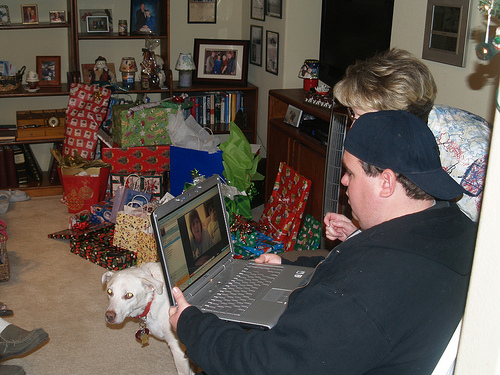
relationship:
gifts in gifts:
[37, 78, 331, 268] [37, 78, 331, 268]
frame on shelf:
[180, 34, 257, 94] [27, 6, 266, 142]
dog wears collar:
[98, 250, 192, 355] [107, 251, 158, 358]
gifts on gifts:
[37, 78, 331, 268] [37, 78, 331, 268]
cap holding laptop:
[167, 108, 489, 344] [133, 176, 321, 335]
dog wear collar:
[98, 250, 192, 355] [107, 251, 158, 358]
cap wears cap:
[167, 108, 489, 344] [338, 98, 485, 223]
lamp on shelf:
[106, 49, 225, 116] [27, 6, 266, 142]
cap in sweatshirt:
[167, 108, 489, 344] [171, 227, 460, 353]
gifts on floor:
[37, 78, 331, 268] [15, 98, 175, 370]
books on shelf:
[165, 89, 257, 140] [27, 6, 266, 142]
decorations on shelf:
[87, 48, 201, 96] [27, 6, 266, 142]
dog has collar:
[98, 250, 192, 355] [107, 251, 158, 358]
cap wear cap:
[167, 108, 489, 344] [338, 98, 485, 223]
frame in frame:
[180, 34, 257, 94] [170, 34, 252, 77]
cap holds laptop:
[167, 108, 489, 344] [133, 176, 321, 335]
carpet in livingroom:
[9, 199, 115, 328] [3, 3, 460, 369]